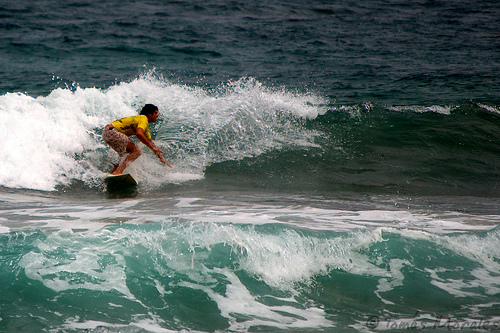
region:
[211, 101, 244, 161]
part of a water splash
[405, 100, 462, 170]
some water waves on the water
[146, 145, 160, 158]
right hand of the swimmer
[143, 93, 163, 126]
head of the swimmer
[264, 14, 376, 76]
more calm part of the ocean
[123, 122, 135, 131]
part of the yellow top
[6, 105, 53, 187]
part of white water splash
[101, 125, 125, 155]
part of a short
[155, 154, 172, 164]
left hand of the swimmer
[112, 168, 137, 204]
part of the swimming board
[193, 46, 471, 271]
this is an ocean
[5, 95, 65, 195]
the water is raised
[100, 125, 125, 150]
the man is in a pair of shorts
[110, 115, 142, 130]
the costume is yellow in color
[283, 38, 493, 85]
the water is wavy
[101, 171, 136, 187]
this is a surfboard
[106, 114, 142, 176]
the man is on the surfboard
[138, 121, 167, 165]
the arms are stretched out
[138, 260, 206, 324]
the water is greenish in color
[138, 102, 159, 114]
the hair is black in color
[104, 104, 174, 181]
this is a man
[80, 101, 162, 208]
the man is sea surfing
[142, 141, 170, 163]
the mans hands are facing the water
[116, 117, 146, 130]
the man has a yellow costume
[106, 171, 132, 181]
he is using a surf board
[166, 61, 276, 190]
the sea is wavy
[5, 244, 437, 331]
water is green in color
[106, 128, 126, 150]
the man is wearing shorts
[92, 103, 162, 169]
the man is bent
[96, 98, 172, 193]
The person in the photo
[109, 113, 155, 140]
The surfer's yellow rash guard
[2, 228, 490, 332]
The water that looks bright green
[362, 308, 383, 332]
The copyright symbol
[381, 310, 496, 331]
The name of the photographer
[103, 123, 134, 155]
The shorts of the surfer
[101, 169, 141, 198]
The surfboard being ridden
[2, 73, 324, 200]
The crest of the wave the surfer is riding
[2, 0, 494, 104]
Open ocean behind the surfer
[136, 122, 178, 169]
The surfer's arms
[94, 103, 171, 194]
a man in a yellow shirt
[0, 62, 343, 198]
white foam on the crest of the wave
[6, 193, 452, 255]
a lot of white sea foam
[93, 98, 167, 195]
a man balancing on a surfboard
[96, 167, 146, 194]
a surfboard floating on the water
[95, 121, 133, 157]
patterned swim trunks on a surfer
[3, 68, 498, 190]
two large waves on the ocean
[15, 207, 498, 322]
a small wave on the ocean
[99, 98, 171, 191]
the man has short dark hair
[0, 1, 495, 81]
some of the water is very calm